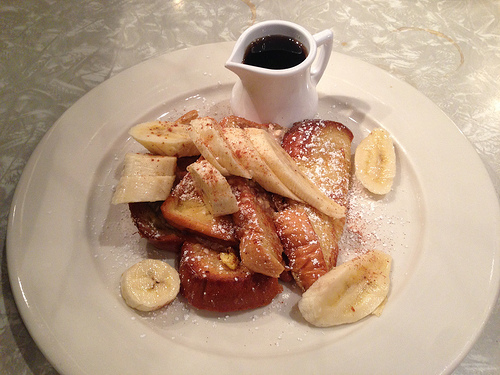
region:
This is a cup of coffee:
[216, 14, 342, 127]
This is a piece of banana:
[293, 254, 399, 341]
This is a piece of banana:
[347, 123, 416, 209]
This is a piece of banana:
[245, 113, 338, 225]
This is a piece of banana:
[115, 256, 185, 318]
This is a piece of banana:
[103, 177, 182, 213]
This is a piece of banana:
[116, 151, 186, 181]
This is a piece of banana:
[120, 111, 205, 160]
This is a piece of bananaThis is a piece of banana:
[182, 157, 239, 219]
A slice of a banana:
[122, 258, 180, 315]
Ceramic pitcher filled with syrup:
[224, 19, 338, 127]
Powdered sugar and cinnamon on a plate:
[348, 196, 405, 247]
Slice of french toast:
[282, 110, 357, 282]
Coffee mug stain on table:
[385, 23, 468, 79]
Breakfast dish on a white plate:
[12, 17, 492, 374]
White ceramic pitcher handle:
[309, 27, 337, 88]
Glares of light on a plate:
[5, 201, 38, 316]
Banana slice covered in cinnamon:
[130, 117, 197, 157]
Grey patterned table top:
[0, 1, 498, 23]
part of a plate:
[418, 184, 446, 235]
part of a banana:
[351, 253, 363, 265]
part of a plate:
[421, 280, 438, 314]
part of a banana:
[315, 250, 355, 327]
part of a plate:
[448, 203, 488, 267]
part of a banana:
[323, 213, 351, 302]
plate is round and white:
[2, 17, 491, 365]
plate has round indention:
[78, 83, 445, 342]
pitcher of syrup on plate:
[193, 5, 360, 127]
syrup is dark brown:
[225, 25, 315, 79]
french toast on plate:
[83, 94, 404, 330]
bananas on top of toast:
[94, 101, 410, 343]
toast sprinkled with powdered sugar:
[265, 118, 375, 272]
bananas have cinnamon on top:
[136, 117, 272, 197]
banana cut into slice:
[115, 258, 191, 313]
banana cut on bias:
[205, 100, 351, 221]